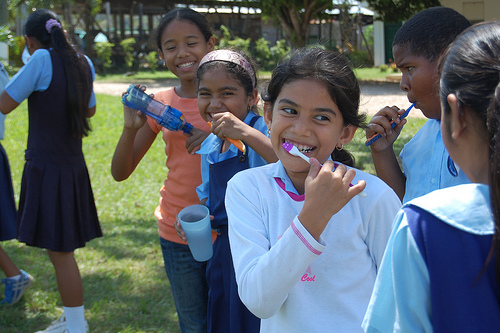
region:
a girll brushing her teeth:
[257, 70, 466, 330]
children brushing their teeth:
[144, 40, 486, 278]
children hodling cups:
[164, 39, 472, 266]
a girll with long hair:
[25, 29, 114, 171]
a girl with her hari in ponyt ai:
[26, 9, 96, 189]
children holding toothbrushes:
[92, 46, 490, 281]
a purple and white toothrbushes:
[278, 114, 351, 190]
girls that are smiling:
[227, 54, 364, 236]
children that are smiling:
[139, 38, 344, 270]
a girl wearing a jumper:
[14, 17, 115, 242]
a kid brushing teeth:
[221, 40, 403, 330]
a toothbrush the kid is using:
[278, 139, 368, 200]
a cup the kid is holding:
[174, 202, 216, 264]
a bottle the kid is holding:
[118, 79, 197, 136]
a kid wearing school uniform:
[1, 5, 103, 331]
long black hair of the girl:
[52, 26, 97, 143]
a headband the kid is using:
[194, 47, 259, 90]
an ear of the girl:
[444, 90, 468, 142]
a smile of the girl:
[173, 57, 198, 72]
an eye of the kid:
[310, 111, 332, 127]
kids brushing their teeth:
[176, 5, 471, 331]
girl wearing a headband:
[176, 45, 278, 332]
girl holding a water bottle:
[108, 6, 215, 331]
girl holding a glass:
[174, 45, 281, 331]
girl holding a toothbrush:
[226, 44, 405, 330]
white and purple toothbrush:
[278, 141, 367, 199]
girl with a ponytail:
[1, 7, 110, 332]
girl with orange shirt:
[109, 5, 212, 331]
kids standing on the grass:
[2, 3, 499, 329]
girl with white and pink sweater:
[224, 45, 406, 331]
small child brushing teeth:
[259, 69, 379, 320]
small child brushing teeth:
[187, 60, 264, 317]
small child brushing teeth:
[134, 10, 221, 305]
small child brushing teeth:
[22, 18, 78, 330]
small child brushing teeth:
[383, 23, 440, 128]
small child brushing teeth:
[439, 51, 496, 286]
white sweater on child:
[225, 155, 404, 308]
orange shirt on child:
[162, 95, 206, 244]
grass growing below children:
[108, 207, 171, 329]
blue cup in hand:
[183, 195, 218, 253]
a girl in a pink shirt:
[241, 48, 384, 330]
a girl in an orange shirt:
[140, 13, 210, 172]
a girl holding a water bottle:
[128, 5, 194, 162]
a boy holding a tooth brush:
[368, 15, 443, 147]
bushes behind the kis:
[82, 23, 278, 57]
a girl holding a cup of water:
[180, 62, 252, 259]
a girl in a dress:
[12, 16, 129, 315]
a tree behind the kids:
[270, 4, 319, 36]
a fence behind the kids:
[91, 6, 288, 53]